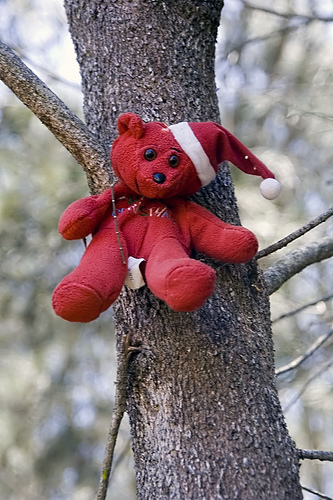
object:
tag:
[124, 255, 146, 289]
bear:
[52, 112, 281, 326]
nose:
[153, 172, 166, 184]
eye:
[144, 148, 158, 161]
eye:
[169, 154, 180, 168]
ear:
[118, 112, 144, 140]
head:
[109, 111, 202, 199]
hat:
[167, 121, 281, 201]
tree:
[0, 0, 333, 500]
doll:
[51, 112, 281, 323]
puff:
[259, 177, 281, 200]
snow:
[103, 456, 144, 497]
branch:
[0, 40, 109, 186]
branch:
[293, 448, 332, 460]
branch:
[254, 206, 331, 259]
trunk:
[62, 0, 304, 499]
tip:
[258, 169, 282, 203]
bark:
[62, 0, 305, 500]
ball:
[259, 177, 281, 200]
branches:
[261, 236, 333, 294]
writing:
[112, 196, 171, 221]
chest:
[112, 194, 172, 219]